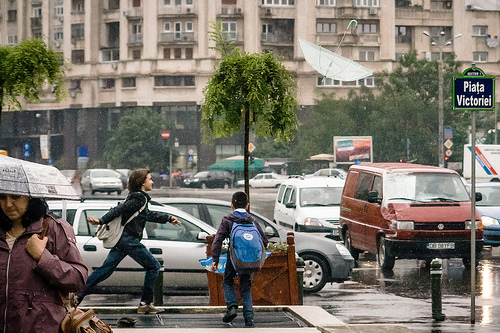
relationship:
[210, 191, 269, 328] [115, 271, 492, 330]
boy crossing street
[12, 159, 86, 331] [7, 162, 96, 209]
woman carrying umbrella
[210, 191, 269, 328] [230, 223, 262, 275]
boy wearing backpack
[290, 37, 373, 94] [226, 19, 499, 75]
umbrella in sky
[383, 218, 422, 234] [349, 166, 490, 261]
headlight on van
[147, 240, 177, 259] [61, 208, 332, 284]
handle on car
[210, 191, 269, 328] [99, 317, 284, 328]
boy on sidewalk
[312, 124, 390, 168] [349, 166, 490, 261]
billboard behind van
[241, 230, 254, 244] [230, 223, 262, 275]
emblem on backpack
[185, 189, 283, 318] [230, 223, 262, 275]
boy wearing backpack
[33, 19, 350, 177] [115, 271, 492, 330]
building across street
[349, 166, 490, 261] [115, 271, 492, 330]
van on street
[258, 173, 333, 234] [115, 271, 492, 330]
van on street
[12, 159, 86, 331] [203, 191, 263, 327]
woman to left of child